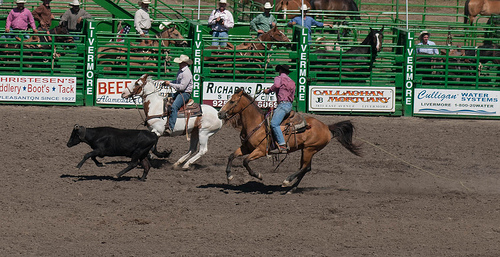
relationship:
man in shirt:
[249, 55, 306, 202] [268, 69, 308, 100]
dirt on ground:
[355, 172, 410, 207] [159, 156, 435, 237]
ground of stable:
[159, 156, 435, 237] [30, 45, 421, 205]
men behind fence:
[125, 10, 367, 48] [107, 24, 416, 99]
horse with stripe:
[324, 31, 392, 91] [362, 22, 381, 51]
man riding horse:
[268, 57, 302, 145] [224, 74, 330, 167]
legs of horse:
[224, 145, 311, 188] [213, 88, 363, 198]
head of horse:
[214, 89, 252, 120] [213, 88, 363, 198]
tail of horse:
[331, 120, 365, 155] [220, 93, 369, 194]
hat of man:
[174, 52, 195, 63] [160, 51, 195, 131]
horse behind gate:
[361, 25, 392, 55] [303, 4, 414, 110]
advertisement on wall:
[311, 84, 401, 117] [9, 15, 483, 114]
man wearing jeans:
[167, 54, 193, 132] [163, 92, 190, 132]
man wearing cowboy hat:
[167, 54, 193, 132] [172, 50, 192, 62]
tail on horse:
[331, 120, 361, 157] [213, 88, 363, 198]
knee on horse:
[226, 153, 236, 162] [213, 88, 363, 198]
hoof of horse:
[226, 170, 235, 187] [220, 93, 369, 194]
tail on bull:
[151, 135, 174, 164] [66, 120, 176, 180]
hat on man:
[273, 62, 289, 71] [263, 60, 294, 150]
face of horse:
[371, 29, 382, 54] [344, 20, 383, 78]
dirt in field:
[4, 105, 484, 254] [7, 102, 480, 252]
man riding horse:
[166, 58, 191, 131] [125, 78, 225, 162]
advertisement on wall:
[307, 80, 397, 111] [304, 15, 409, 122]